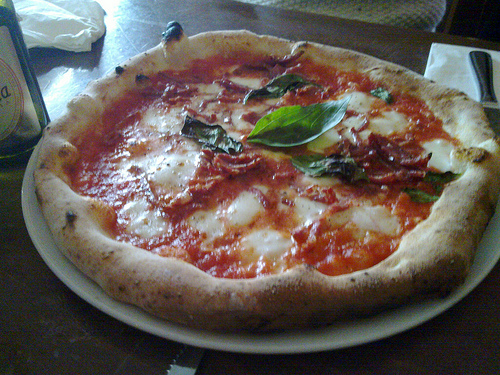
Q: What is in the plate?
A: Pizza.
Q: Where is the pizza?
A: On a white plate.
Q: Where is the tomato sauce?
A: Inside the pizza.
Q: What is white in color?
A: Melted cheese.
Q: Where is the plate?
A: On the table.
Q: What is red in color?
A: Tomato sauce.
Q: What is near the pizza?
A: A knife.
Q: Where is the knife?
A: On the table.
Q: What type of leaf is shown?
A: Basil.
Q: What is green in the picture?
A: Basil.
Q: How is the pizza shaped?
A: Roundly.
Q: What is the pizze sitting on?
A: A plate.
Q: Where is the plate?
A: A table.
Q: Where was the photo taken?
A: A kitchen.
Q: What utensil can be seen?
A: Knife.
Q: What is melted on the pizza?
A: Cheese.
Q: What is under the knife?
A: Napkin.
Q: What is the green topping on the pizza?
A: Spinach.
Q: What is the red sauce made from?
A: Tomatoes.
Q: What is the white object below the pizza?
A: A plate.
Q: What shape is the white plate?
A: A circle.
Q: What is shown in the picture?
A: A pizza.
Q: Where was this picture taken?
A: A restaurant.